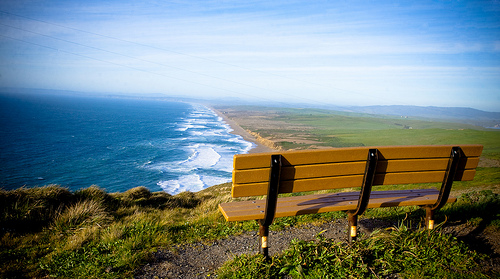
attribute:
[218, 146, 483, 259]
bench — wooden, brown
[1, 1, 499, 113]
sky — blue, white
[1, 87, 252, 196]
sea — blue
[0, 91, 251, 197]
ocean — blue, beautiful